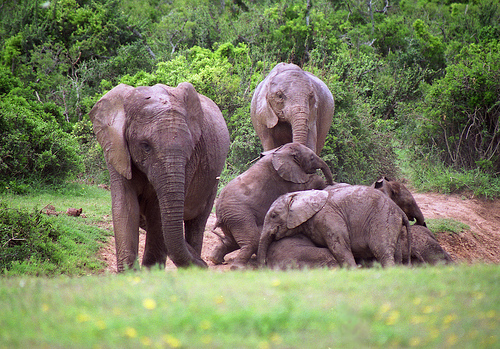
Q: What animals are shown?
A: Elephants.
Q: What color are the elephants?
A: Grey.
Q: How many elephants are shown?
A: Five.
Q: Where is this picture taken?
A: The jungle.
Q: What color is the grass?
A: Green.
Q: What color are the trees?
A: Green.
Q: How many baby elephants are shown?
A: Two.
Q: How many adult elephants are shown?
A: Three.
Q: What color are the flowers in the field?
A: Yellow.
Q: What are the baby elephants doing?
A: Playing.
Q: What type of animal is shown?
A: Elephants.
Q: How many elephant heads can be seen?
A: 5.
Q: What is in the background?
A: Trees and shrubs.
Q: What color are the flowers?
A: Yellow.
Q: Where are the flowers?
A: Field.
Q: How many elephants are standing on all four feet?
A: 2.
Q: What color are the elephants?
A: Gray.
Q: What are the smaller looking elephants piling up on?
A: Each other.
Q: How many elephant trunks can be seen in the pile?
A: 3.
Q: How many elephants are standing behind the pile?
A: One.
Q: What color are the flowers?
A: Yellow.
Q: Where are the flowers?
A: Field.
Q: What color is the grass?
A: Green.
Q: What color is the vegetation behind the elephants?
A: Green.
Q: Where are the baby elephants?
A: On the pile.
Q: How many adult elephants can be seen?
A: 2.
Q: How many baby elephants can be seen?
A: Four.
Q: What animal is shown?
A: Elephants.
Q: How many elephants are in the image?
A: Approximately 6.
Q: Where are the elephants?
A: In the wild.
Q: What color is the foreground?
A: Green.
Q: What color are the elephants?
A: Brown and grey.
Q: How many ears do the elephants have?
A: Two.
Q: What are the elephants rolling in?
A: Mud.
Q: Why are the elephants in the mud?
A: To keep cool.